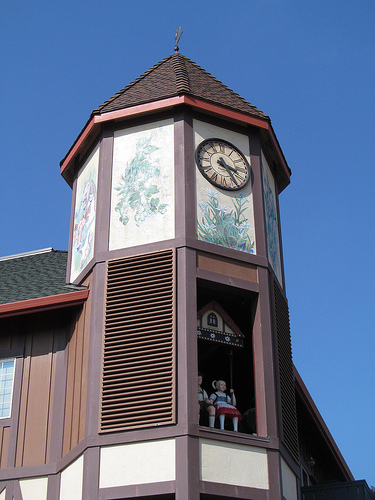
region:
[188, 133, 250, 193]
round clock on the building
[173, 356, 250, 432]
toy figures in building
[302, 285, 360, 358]
blue sky above building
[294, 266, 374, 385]
sky with no clouds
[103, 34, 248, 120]
top of the building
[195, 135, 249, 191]
clock is white and black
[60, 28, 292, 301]
tower is brown and tall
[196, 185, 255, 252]
panels have florel designs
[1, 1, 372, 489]
sky is blue and clear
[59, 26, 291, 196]
building has a large steeple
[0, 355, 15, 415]
building has as clear window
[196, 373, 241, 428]
dolls are german and large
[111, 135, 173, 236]
mural on the brown clock tower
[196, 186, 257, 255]
mural on the brown clock tower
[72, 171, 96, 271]
mural on the brown clock tower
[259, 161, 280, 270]
mural on the brown clock tower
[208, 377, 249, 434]
doll on the brown clock tower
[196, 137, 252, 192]
clock on the brown clock tower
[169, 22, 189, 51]
weather vain on the brown clock tower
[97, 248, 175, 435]
grate on the brown clock tower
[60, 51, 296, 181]
dome on the brown clock tower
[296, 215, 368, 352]
the sky is clear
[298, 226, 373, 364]
the sky is clear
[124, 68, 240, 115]
the roof is tiled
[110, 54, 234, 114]
the roof is tiled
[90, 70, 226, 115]
the roof is tiled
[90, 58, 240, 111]
the roof is tiled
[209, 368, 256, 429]
The girl doll sitting down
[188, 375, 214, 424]
The boy doll sitting down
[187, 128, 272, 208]
The clock close to the top of the building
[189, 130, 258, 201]
The clock is dirty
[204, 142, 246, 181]
The face of the clock is white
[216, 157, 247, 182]
The hand of the clock is black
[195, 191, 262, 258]
The floral design below the clock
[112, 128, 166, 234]
The floral design next to the clock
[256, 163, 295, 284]
The floral design barely visible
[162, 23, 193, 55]
The compass to the top of the buildig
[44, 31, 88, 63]
a view of sky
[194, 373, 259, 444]
a view of doll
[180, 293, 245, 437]
a view of girl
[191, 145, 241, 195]
a view of clock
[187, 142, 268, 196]
a clock in the top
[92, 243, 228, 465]
a view of wall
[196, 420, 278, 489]
a view of buidling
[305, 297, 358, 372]
a view of clouds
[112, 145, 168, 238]
a view of design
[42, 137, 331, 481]
a view of pillar